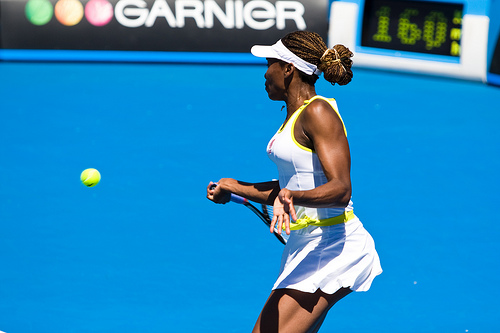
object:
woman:
[207, 31, 383, 332]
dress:
[266, 95, 383, 293]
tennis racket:
[224, 184, 290, 249]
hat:
[249, 38, 319, 79]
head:
[263, 29, 324, 102]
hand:
[269, 186, 300, 234]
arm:
[295, 102, 354, 207]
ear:
[282, 62, 295, 79]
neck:
[283, 76, 318, 114]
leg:
[255, 238, 356, 331]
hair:
[281, 28, 354, 87]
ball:
[80, 168, 100, 188]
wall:
[1, 49, 498, 327]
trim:
[281, 96, 347, 154]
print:
[112, 0, 308, 29]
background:
[1, 3, 325, 54]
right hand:
[207, 177, 234, 204]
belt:
[287, 211, 357, 232]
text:
[373, 7, 463, 54]